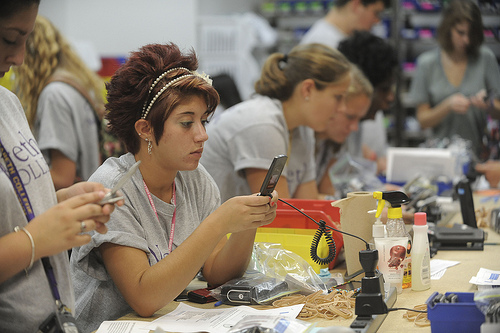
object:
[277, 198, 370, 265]
cord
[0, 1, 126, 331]
girl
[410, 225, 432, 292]
clear bottle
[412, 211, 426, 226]
pink cap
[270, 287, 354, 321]
rubber bands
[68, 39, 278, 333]
woman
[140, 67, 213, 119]
head band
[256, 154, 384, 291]
phone cord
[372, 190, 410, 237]
ground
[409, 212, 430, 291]
polish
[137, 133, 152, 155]
three earrings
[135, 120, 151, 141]
ear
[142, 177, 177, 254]
lanyard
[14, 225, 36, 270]
bracelet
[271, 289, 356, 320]
pile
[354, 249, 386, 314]
stamp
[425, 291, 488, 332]
container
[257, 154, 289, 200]
phone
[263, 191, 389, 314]
charger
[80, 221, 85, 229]
ring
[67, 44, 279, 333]
girl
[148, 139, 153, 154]
earring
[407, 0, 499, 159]
woman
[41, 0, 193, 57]
white wall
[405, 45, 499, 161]
shirt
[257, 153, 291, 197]
cell phone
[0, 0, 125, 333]
woman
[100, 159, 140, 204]
cell phone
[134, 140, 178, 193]
neck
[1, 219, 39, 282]
wrist